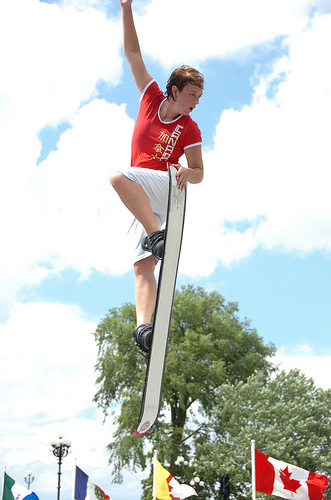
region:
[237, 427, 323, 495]
This is a flag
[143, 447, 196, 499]
This is a flag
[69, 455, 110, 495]
This is a flag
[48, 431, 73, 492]
This is a flag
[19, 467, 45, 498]
This is a flag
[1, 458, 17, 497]
This is a flag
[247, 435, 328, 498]
red and white canadian flag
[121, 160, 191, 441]
white board with black and red trim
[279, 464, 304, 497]
red maple leaf on a flag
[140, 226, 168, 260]
a boy's left foot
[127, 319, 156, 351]
a boy's right foot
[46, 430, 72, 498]
a street lamp with white globes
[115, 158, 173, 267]
white shorts on a boy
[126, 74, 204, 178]
a boy's red and white shirt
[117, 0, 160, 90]
right arm in the air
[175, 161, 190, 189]
left hand on the board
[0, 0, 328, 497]
white clouds in blue sky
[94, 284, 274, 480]
green leaves on tree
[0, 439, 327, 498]
row of four flags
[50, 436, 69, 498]
lights on top of pole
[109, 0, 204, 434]
jumping girl on snowboard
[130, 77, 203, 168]
red shirt with short sleeves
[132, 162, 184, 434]
hand on bottom of snowboard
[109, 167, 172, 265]
white shorts on legs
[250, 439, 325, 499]
red and white flag on pole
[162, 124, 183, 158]
word with stacked letters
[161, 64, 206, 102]
a woman's short cut brown hair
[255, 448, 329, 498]
a red and white flag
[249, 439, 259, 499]
part of a white flag pole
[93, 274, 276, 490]
a large green tree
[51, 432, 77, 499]
part of a tall street lamp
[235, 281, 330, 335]
part of a blue sky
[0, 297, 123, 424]
a large white cloud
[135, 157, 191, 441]
a long ski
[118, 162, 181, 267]
a woman's white shorts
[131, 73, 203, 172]
a woman's red and white shirt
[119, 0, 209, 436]
a woman performs on a snowboard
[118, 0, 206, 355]
a girl with short hair does a trick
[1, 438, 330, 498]
flags of different countries in a row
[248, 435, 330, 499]
a canadian flag flowing in the wind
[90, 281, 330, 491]
a couple of trees obscured by flags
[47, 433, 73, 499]
a street light over a blue sky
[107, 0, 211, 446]
a woman does a jump on a snowboard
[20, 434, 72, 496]
old style street lights on a clear day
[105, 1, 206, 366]
an athlete jumps in the air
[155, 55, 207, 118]
a short haired woman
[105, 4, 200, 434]
woman performing snowboarding trick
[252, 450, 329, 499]
red and white Canadian flag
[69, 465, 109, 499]
blue and white flag